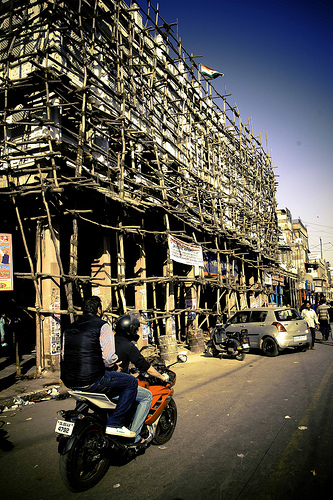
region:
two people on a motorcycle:
[41, 294, 187, 493]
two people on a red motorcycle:
[52, 293, 186, 491]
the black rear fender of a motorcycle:
[52, 408, 112, 490]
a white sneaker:
[103, 421, 138, 438]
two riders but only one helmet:
[51, 296, 184, 486]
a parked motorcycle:
[203, 317, 251, 365]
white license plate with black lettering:
[48, 419, 77, 435]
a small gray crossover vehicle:
[214, 306, 312, 354]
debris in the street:
[231, 408, 309, 465]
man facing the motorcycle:
[296, 302, 321, 344]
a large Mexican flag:
[190, 49, 241, 94]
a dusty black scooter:
[188, 315, 256, 368]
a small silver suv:
[200, 303, 317, 359]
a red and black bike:
[47, 344, 193, 476]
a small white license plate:
[47, 417, 78, 443]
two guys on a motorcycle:
[27, 296, 195, 471]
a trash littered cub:
[3, 379, 53, 412]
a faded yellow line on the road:
[274, 355, 330, 489]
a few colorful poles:
[260, 279, 325, 316]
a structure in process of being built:
[4, 32, 312, 317]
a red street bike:
[55, 354, 187, 492]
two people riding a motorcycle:
[50, 294, 176, 492]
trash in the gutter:
[1, 384, 58, 417]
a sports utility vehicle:
[211, 306, 309, 356]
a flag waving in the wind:
[196, 61, 222, 84]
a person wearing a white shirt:
[300, 301, 318, 347]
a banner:
[166, 233, 203, 267]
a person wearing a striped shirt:
[316, 299, 331, 341]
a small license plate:
[54, 418, 74, 436]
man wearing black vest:
[61, 306, 114, 385]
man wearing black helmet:
[111, 309, 150, 347]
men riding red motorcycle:
[51, 277, 220, 456]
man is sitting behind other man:
[40, 279, 144, 409]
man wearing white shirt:
[297, 307, 315, 324]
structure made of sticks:
[0, 0, 289, 343]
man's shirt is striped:
[317, 303, 327, 316]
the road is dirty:
[2, 368, 317, 495]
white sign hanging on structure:
[159, 228, 233, 275]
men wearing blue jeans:
[78, 367, 156, 448]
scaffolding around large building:
[2, 1, 278, 367]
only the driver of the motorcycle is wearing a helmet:
[70, 293, 176, 395]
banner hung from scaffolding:
[149, 211, 226, 280]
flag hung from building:
[182, 48, 233, 106]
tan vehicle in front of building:
[199, 243, 312, 358]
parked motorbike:
[190, 299, 256, 361]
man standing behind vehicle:
[281, 293, 319, 346]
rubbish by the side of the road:
[0, 370, 65, 434]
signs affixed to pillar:
[31, 245, 65, 364]